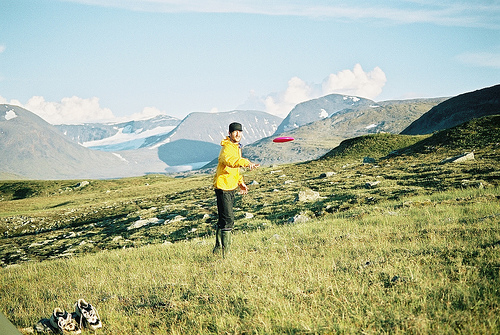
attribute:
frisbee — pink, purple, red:
[271, 134, 295, 144]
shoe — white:
[75, 296, 104, 330]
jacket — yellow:
[214, 138, 249, 192]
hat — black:
[229, 122, 244, 133]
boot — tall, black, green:
[221, 228, 234, 262]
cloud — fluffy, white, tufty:
[19, 95, 122, 128]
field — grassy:
[2, 170, 498, 333]